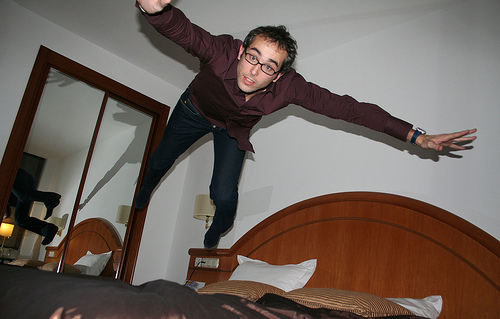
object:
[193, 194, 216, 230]
lamp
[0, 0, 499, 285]
wall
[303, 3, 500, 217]
ground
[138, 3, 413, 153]
shirt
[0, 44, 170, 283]
mirror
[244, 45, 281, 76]
glasses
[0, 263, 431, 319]
sheets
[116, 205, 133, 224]
lampshade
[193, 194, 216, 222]
lampshade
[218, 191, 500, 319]
headboard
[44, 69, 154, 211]
shadow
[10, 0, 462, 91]
ceiling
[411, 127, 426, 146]
watch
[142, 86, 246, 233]
jeans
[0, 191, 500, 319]
bed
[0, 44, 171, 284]
closet door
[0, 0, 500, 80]
air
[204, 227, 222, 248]
sock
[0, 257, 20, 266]
table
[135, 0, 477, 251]
man